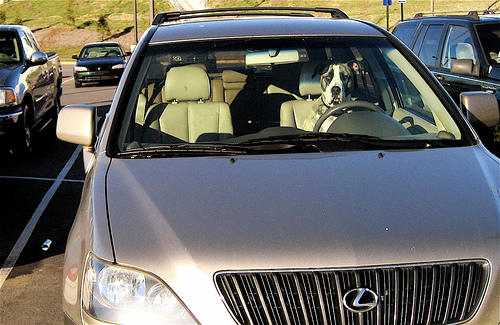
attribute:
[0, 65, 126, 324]
ground — here, brown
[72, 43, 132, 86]
car — here, black, small, parked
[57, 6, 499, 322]
vehicle — grey, suv, four door, silver, silver colored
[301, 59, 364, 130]
dog — black, white, sitting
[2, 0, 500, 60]
grass — here, green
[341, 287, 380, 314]
lexus logo — silver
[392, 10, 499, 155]
suv — black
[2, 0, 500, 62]
hill — grassy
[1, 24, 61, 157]
truck — black, black colored, parked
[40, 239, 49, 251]
can — trash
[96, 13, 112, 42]
tree — small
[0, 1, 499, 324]
photo — daytime, outdoors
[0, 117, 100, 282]
line — white